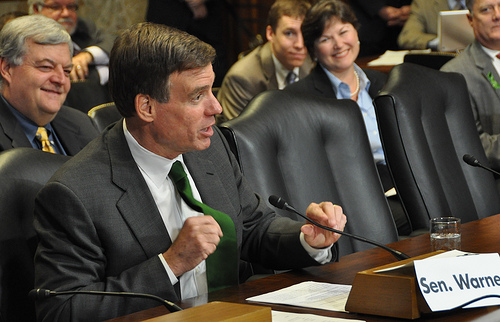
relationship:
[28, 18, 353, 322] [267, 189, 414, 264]
man holding microphone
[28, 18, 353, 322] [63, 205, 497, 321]
man sitting at table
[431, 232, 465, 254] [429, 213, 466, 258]
water in glass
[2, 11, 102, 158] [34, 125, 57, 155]
man wearing tie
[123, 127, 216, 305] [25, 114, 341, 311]
shirt under jacket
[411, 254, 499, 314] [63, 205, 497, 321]
name tag on table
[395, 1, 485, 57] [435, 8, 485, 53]
person using laptop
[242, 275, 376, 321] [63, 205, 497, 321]
paper on table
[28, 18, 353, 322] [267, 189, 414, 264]
man near microphone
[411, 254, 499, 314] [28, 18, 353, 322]
name tag in front of man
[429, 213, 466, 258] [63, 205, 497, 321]
glass on table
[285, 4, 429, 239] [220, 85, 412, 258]
women behind chair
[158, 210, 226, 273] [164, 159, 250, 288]
hand holding tie